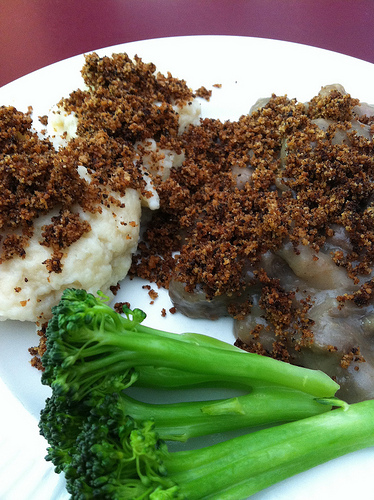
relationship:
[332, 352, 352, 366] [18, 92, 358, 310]
bits sprinkled over food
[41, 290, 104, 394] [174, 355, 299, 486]
florets on spears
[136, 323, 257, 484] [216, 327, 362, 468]
stalks on spears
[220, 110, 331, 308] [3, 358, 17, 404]
food on plate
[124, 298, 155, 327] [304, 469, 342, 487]
broccolli on plate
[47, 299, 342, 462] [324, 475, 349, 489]
brocolli on plate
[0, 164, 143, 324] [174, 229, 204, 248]
food with seasoning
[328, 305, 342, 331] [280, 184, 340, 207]
grave with seasoning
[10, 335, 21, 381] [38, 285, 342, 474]
plate with brocolli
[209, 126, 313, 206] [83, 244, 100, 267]
seasoning on potatoes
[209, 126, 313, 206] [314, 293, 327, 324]
seasoning on gravy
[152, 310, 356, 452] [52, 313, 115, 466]
stem of broccoli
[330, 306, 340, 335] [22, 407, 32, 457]
gravy on plate